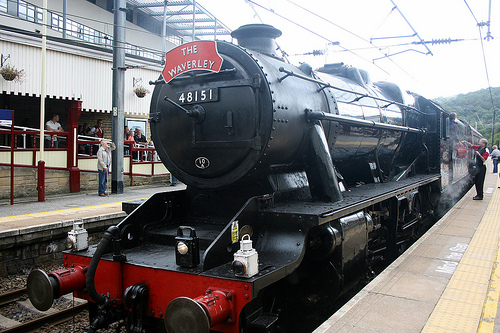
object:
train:
[27, 23, 488, 333]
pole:
[11, 109, 15, 205]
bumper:
[26, 264, 236, 333]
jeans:
[98, 163, 110, 195]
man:
[97, 139, 117, 196]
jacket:
[97, 142, 117, 170]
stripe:
[0, 180, 188, 237]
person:
[78, 119, 104, 156]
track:
[0, 269, 87, 333]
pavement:
[313, 158, 499, 333]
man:
[455, 138, 489, 200]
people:
[45, 113, 162, 162]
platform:
[0, 0, 165, 235]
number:
[179, 89, 213, 103]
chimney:
[230, 24, 282, 56]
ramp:
[0, 121, 182, 183]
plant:
[0, 62, 30, 85]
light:
[175, 226, 200, 268]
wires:
[238, 0, 498, 72]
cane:
[101, 167, 109, 196]